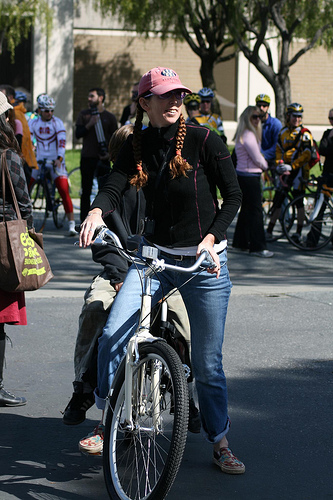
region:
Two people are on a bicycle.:
[44, 51, 235, 489]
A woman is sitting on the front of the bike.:
[74, 56, 240, 473]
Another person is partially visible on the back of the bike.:
[55, 263, 118, 423]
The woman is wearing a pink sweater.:
[230, 100, 268, 256]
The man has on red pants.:
[26, 169, 75, 226]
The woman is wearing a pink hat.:
[133, 63, 191, 97]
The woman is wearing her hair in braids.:
[126, 90, 193, 187]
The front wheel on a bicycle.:
[279, 189, 330, 250]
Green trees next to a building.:
[92, 0, 329, 109]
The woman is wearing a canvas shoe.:
[196, 440, 257, 479]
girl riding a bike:
[60, 67, 246, 498]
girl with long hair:
[231, 102, 275, 259]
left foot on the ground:
[209, 437, 247, 474]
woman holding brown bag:
[0, 90, 52, 409]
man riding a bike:
[29, 93, 78, 237]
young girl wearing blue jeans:
[77, 66, 247, 478]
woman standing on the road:
[233, 96, 275, 269]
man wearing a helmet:
[264, 101, 320, 244]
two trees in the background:
[87, 0, 331, 125]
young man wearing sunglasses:
[28, 91, 76, 237]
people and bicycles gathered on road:
[7, 28, 322, 418]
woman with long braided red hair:
[123, 62, 193, 187]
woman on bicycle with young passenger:
[54, 59, 242, 488]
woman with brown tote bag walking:
[0, 90, 50, 408]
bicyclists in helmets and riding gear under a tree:
[254, 12, 312, 249]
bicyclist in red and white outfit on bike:
[20, 89, 72, 233]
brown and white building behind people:
[33, 4, 320, 117]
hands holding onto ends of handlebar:
[69, 203, 219, 276]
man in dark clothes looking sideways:
[72, 83, 112, 208]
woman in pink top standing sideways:
[229, 102, 266, 255]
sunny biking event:
[0, 16, 326, 485]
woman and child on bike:
[63, 66, 250, 491]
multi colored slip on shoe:
[192, 446, 246, 476]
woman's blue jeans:
[89, 261, 226, 434]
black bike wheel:
[99, 333, 186, 497]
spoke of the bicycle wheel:
[116, 362, 174, 494]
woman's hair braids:
[130, 113, 191, 187]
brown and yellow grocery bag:
[3, 215, 50, 295]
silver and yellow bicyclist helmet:
[285, 102, 304, 113]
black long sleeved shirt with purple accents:
[93, 124, 239, 241]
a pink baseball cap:
[137, 68, 195, 99]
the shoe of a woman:
[212, 444, 251, 472]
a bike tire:
[104, 337, 192, 498]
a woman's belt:
[158, 247, 194, 262]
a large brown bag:
[1, 159, 56, 291]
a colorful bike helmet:
[284, 101, 304, 114]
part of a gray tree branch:
[229, 19, 308, 122]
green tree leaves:
[103, 0, 194, 48]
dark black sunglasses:
[249, 112, 262, 119]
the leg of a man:
[56, 165, 78, 221]